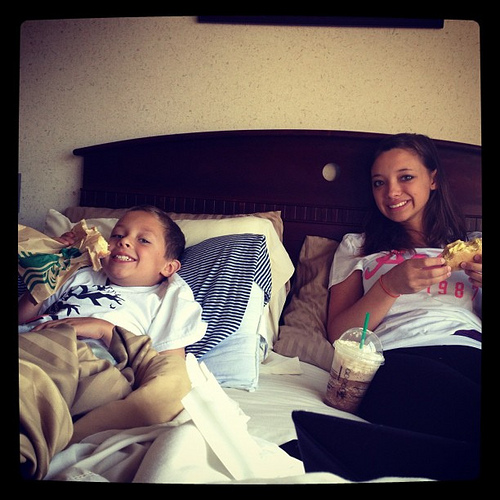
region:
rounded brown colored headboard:
[177, 115, 350, 204]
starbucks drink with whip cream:
[338, 314, 381, 401]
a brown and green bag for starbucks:
[33, 225, 112, 309]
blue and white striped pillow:
[202, 225, 289, 372]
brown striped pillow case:
[273, 239, 325, 375]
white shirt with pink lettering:
[338, 229, 474, 343]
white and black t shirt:
[54, 271, 152, 324]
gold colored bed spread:
[35, 334, 85, 449]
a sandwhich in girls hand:
[438, 242, 480, 293]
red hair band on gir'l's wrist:
[375, 266, 406, 302]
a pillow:
[208, 240, 256, 315]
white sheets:
[212, 385, 272, 466]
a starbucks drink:
[335, 333, 373, 399]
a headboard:
[81, 139, 311, 201]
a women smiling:
[369, 145, 435, 225]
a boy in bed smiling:
[105, 215, 171, 283]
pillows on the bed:
[206, 212, 273, 229]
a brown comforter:
[26, 335, 92, 403]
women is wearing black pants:
[408, 364, 485, 436]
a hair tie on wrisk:
[377, 273, 398, 298]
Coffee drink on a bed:
[326, 310, 386, 415]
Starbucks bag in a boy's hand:
[21, 218, 111, 306]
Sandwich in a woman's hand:
[433, 234, 485, 276]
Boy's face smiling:
[103, 208, 179, 283]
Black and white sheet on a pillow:
[176, 235, 271, 376]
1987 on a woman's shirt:
[423, 275, 482, 302]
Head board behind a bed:
[62, 127, 487, 234]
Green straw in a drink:
[358, 313, 370, 343]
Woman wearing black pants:
[368, 343, 490, 451]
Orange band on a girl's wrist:
[376, 269, 403, 304]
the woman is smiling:
[313, 113, 465, 253]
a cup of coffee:
[318, 289, 395, 404]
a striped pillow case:
[177, 211, 277, 387]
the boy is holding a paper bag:
[4, 210, 159, 340]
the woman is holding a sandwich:
[377, 170, 495, 312]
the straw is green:
[330, 295, 377, 342]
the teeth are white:
[370, 195, 429, 220]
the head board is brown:
[154, 115, 475, 234]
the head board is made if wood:
[92, 117, 492, 217]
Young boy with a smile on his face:
[100, 206, 187, 287]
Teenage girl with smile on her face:
[365, 141, 435, 225]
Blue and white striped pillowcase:
[190, 235, 275, 347]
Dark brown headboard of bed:
[67, 128, 361, 213]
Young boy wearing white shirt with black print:
[44, 209, 206, 345]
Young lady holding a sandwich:
[360, 130, 485, 308]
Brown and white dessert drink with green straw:
[324, 313, 384, 415]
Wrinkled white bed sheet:
[239, 390, 298, 409]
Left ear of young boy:
[158, 258, 184, 275]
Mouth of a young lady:
[383, 198, 410, 213]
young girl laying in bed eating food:
[322, 130, 494, 482]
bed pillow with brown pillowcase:
[267, 230, 341, 371]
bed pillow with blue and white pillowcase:
[177, 234, 275, 392]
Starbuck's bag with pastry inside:
[14, 221, 109, 303]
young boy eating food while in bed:
[24, 201, 210, 482]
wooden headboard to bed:
[67, 126, 485, 270]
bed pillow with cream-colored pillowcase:
[54, 216, 298, 353]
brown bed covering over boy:
[19, 318, 190, 480]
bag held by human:
[19, 215, 114, 307]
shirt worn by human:
[41, 260, 208, 355]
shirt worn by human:
[329, 225, 480, 350]